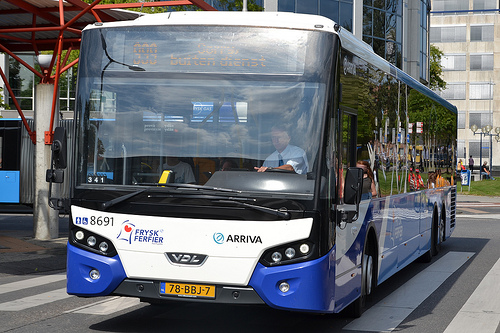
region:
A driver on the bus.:
[242, 113, 318, 195]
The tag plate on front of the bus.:
[157, 269, 237, 304]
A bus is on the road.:
[67, 16, 466, 293]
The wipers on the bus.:
[113, 168, 300, 228]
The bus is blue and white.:
[243, 44, 484, 286]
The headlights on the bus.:
[76, 218, 311, 263]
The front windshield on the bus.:
[99, 67, 312, 180]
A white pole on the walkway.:
[17, 77, 69, 241]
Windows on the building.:
[441, 16, 486, 117]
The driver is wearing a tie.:
[272, 148, 285, 178]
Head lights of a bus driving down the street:
[70, 229, 317, 269]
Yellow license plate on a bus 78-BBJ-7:
[158, 279, 219, 298]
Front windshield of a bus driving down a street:
[71, 25, 329, 216]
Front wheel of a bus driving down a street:
[358, 239, 386, 308]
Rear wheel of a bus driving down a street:
[425, 210, 446, 252]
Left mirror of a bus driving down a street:
[341, 165, 368, 210]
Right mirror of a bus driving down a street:
[47, 127, 71, 171]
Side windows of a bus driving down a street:
[361, 71, 460, 193]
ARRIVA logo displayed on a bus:
[211, 230, 266, 246]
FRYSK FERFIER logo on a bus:
[115, 217, 165, 249]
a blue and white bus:
[63, 9, 462, 320]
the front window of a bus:
[71, 26, 331, 198]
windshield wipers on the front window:
[97, 181, 314, 213]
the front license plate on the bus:
[158, 280, 218, 298]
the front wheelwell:
[358, 221, 383, 292]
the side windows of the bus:
[380, 85, 457, 192]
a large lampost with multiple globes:
[471, 123, 498, 173]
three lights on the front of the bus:
[265, 242, 315, 262]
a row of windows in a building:
[432, 23, 498, 45]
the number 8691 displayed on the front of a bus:
[87, 214, 114, 228]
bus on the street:
[57, 13, 473, 320]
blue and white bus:
[59, 17, 469, 324]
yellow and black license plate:
[164, 279, 221, 300]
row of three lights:
[66, 223, 112, 257]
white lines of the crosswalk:
[0, 249, 499, 332]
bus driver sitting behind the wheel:
[239, 128, 316, 179]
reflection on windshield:
[86, 31, 153, 148]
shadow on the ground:
[364, 227, 484, 332]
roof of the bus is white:
[114, 5, 397, 79]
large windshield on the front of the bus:
[61, 26, 329, 216]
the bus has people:
[101, 21, 477, 326]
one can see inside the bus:
[88, 22, 473, 302]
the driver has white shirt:
[256, 149, 316, 184]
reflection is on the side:
[403, 159, 458, 204]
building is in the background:
[348, 6, 445, 66]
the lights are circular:
[260, 237, 319, 269]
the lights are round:
[64, 224, 119, 262]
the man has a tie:
[242, 116, 308, 176]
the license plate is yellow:
[166, 279, 230, 305]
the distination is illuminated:
[131, 46, 275, 75]